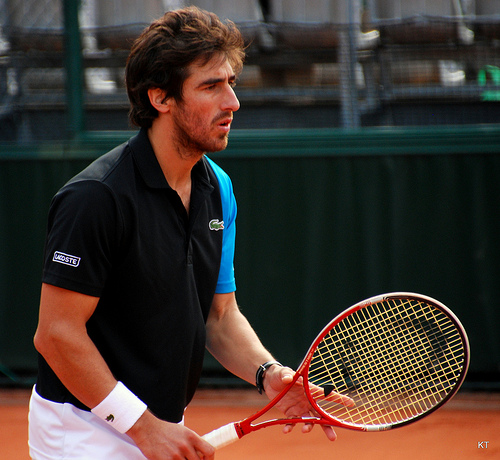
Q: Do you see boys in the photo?
A: No, there are no boys.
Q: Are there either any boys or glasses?
A: No, there are no boys or glasses.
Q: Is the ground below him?
A: Yes, the ground is below a man.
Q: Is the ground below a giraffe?
A: No, the ground is below a man.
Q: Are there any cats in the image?
A: No, there are no cats.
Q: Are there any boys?
A: No, there are no boys.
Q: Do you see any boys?
A: No, there are no boys.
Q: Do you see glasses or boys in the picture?
A: No, there are no boys or glasses.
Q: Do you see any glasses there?
A: No, there are no glasses.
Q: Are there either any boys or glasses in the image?
A: No, there are no glasses or boys.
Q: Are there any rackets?
A: Yes, there is a racket.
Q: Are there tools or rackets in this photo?
A: Yes, there is a racket.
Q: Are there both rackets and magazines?
A: No, there is a racket but no magazines.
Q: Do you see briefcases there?
A: No, there are no briefcases.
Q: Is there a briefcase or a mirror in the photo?
A: No, there are no briefcases or mirrors.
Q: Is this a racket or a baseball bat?
A: This is a racket.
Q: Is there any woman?
A: No, there are no women.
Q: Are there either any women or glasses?
A: No, there are no women or glasses.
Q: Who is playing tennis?
A: The man is playing tennis.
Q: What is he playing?
A: The man is playing tennis.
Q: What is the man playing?
A: The man is playing tennis.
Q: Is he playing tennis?
A: Yes, the man is playing tennis.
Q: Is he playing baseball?
A: No, the man is playing tennis.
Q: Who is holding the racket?
A: The man is holding the racket.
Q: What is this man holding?
A: The man is holding the tennis racket.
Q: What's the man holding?
A: The man is holding the tennis racket.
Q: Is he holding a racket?
A: Yes, the man is holding a racket.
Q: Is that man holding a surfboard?
A: No, the man is holding a racket.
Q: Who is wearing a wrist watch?
A: The man is wearing a wrist watch.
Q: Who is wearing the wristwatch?
A: The man is wearing a wrist watch.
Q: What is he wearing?
A: The man is wearing a wrist watch.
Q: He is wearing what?
A: The man is wearing a wrist watch.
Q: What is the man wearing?
A: The man is wearing a wrist watch.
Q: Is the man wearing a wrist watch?
A: Yes, the man is wearing a wrist watch.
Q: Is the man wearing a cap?
A: No, the man is wearing a wrist watch.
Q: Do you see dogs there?
A: No, there are no dogs.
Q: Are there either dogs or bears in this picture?
A: No, there are no dogs or bears.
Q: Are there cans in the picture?
A: No, there are no cans.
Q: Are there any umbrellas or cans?
A: No, there are no cans or umbrellas.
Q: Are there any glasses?
A: No, there are no glasses.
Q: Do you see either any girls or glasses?
A: No, there are no glasses or girls.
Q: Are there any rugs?
A: No, there are no rugs.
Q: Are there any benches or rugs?
A: No, there are no rugs or benches.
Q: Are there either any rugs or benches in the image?
A: No, there are no rugs or benches.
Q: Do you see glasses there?
A: No, there are no glasses.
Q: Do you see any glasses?
A: No, there are no glasses.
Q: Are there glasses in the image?
A: No, there are no glasses.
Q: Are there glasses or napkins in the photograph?
A: No, there are no glasses or napkins.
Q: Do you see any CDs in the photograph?
A: No, there are no cds.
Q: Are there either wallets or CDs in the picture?
A: No, there are no CDs or wallets.